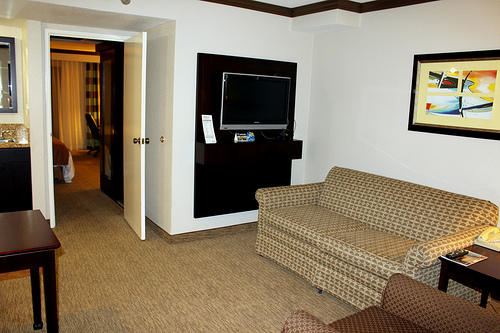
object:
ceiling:
[198, 0, 444, 22]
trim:
[204, 0, 444, 18]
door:
[43, 29, 150, 243]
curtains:
[52, 58, 89, 152]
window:
[49, 48, 102, 153]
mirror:
[0, 35, 18, 113]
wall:
[0, 25, 22, 122]